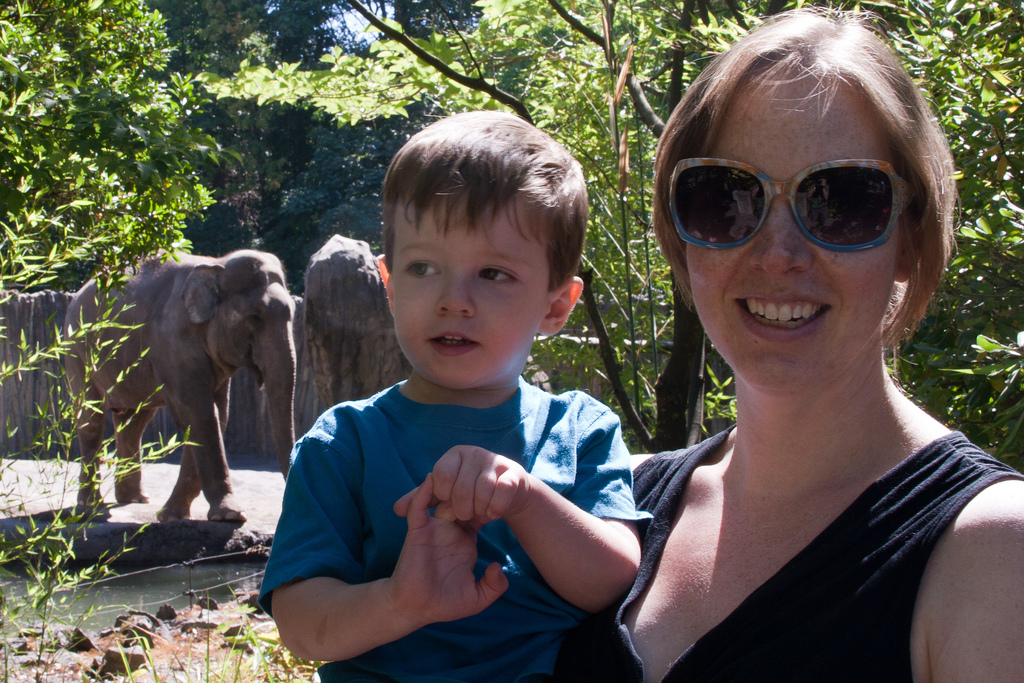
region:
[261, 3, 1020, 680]
A woman holding a young boy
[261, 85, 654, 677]
The boy is wearing a blue shirt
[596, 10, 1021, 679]
The woman is wearing a black tank top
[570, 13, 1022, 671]
The woman is wearing sunglasses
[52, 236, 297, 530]
An elephant in the background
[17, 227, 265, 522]
the elephant is in an enclosure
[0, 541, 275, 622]
A water area in front of the elephant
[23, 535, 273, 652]
A metal wire strung across the area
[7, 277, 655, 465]
A fence behind the elephants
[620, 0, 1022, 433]
Woman wearing colorful sunglasses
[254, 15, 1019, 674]
Woman holding a little boy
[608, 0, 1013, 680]
Woman wearing a black sleeveless shirt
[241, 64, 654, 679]
Little boy wearing a blue shirt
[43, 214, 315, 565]
Elephant walking down a path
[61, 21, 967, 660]
Elephant walking behind woman holding a little boy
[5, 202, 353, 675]
Elephant walking by some water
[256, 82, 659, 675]
Little boy holding his fingers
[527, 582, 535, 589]
An Asian woman is holding a purse.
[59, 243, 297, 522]
elephant standing next to stone wall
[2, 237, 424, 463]
stone wall is gray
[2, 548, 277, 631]
small pond next to elephant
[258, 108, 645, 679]
young boy wearing blue shirt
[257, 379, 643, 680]
short-sleeved shirt is blue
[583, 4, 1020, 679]
woman carrying small boy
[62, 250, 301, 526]
elephant has long trunk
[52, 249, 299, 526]
elephant has four gray legs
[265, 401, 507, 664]
boy's right arm has birthmark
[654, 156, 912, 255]
Sunglasses on woman's face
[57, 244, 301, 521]
Elephant walking in enclosure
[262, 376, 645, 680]
Blue shirt on boy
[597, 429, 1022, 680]
Black shirt on woman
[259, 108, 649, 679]
Small boy being held by woman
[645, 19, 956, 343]
Short hair on woman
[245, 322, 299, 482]
Trunk on walking elephant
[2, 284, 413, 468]
Wooden fence inside elephant enclosure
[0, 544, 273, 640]
Pool of water in elephant enclosure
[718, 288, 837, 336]
Smile on woman's face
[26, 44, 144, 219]
The leaves are green.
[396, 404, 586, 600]
The boy has a blue shirt.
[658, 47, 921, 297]
The woman is wearing sunglasses.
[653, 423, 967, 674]
The woman is wearing black.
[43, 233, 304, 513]
An elephant is in the background.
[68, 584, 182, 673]
Rocks are on the ground.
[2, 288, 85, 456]
The fence is on the ground.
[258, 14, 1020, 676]
Woman wearing sunglasses and holding a young boy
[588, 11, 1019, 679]
Woman wearing sunglasses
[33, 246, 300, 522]
Small elephant walking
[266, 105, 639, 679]
Young boy wearing a blue t-shirt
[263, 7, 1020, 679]
Woman and young boy smiling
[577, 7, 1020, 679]
Woman wearing a black dress and sunglasses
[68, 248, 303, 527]
Elephant walking in zoo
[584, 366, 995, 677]
the tank is black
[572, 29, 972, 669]
the woman is happy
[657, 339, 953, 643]
a shadow on neck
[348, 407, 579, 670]
the hand is bending fingers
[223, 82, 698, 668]
the boy is wearing tee shirt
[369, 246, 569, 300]
the eyes are looking sideways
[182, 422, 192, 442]
A flower on a stem.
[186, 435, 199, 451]
A leaf on a stem.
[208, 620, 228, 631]
A leaf on a stem.